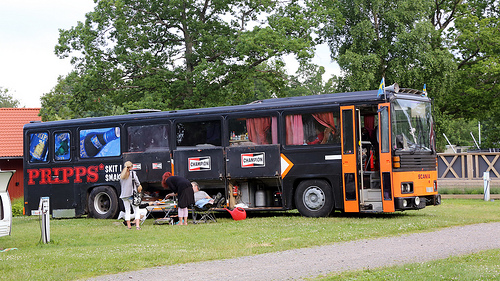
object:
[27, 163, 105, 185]
sign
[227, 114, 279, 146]
window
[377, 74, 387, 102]
flags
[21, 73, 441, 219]
bus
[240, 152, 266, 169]
advertising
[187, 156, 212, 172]
advertising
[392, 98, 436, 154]
window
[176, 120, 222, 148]
window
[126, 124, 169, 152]
window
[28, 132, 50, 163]
window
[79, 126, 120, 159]
window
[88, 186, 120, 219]
tire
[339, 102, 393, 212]
doors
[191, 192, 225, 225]
chair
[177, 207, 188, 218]
pants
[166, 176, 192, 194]
shirt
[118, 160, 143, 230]
person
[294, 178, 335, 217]
wheel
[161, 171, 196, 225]
female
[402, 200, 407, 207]
lighting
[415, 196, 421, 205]
lighting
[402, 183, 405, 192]
lighting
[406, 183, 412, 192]
lighting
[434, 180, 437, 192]
lighting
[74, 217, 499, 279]
pathway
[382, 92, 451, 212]
end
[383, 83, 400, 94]
horn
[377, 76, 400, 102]
corner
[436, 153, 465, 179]
fencing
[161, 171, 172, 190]
hair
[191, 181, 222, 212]
person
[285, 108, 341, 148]
windows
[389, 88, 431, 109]
top